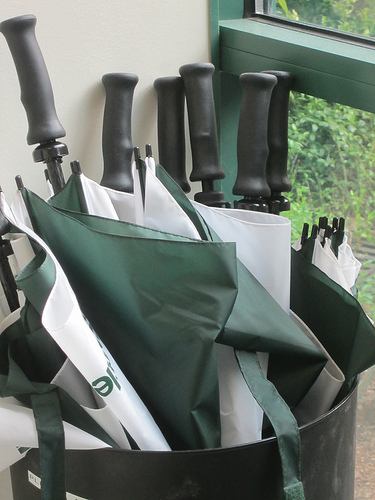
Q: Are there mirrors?
A: No, there are no mirrors.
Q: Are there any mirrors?
A: No, there are no mirrors.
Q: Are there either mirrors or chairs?
A: No, there are no mirrors or chairs.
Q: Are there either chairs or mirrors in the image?
A: No, there are no mirrors or chairs.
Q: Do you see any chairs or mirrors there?
A: No, there are no mirrors or chairs.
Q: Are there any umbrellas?
A: Yes, there is an umbrella.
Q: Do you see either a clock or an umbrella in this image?
A: Yes, there is an umbrella.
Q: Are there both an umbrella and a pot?
A: No, there is an umbrella but no pots.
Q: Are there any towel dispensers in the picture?
A: No, there are no towel dispensers.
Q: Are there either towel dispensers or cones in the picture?
A: No, there are no towel dispensers or cones.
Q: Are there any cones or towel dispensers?
A: No, there are no towel dispensers or cones.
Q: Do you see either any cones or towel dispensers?
A: No, there are no towel dispensers or cones.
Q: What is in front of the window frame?
A: The umbrella is in front of the window frame.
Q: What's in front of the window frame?
A: The umbrella is in front of the window frame.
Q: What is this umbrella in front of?
A: The umbrella is in front of the window frame.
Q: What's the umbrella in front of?
A: The umbrella is in front of the window frame.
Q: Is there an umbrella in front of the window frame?
A: Yes, there is an umbrella in front of the window frame.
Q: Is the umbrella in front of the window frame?
A: Yes, the umbrella is in front of the window frame.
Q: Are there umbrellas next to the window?
A: Yes, there is an umbrella next to the window.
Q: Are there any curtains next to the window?
A: No, there is an umbrella next to the window.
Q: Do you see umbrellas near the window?
A: Yes, there is an umbrella near the window.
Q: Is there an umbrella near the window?
A: Yes, there is an umbrella near the window.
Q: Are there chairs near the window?
A: No, there is an umbrella near the window.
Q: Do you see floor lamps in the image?
A: No, there are no floor lamps.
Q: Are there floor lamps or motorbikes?
A: No, there are no floor lamps or motorbikes.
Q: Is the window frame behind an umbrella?
A: Yes, the window frame is behind an umbrella.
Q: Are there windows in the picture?
A: Yes, there is a window.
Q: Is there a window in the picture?
A: Yes, there is a window.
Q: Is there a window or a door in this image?
A: Yes, there is a window.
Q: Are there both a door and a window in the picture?
A: No, there is a window but no doors.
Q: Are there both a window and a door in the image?
A: No, there is a window but no doors.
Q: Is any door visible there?
A: No, there are no doors.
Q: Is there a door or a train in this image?
A: No, there are no doors or trains.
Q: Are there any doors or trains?
A: No, there are no doors or trains.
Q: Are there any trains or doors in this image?
A: No, there are no doors or trains.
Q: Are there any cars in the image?
A: No, there are no cars.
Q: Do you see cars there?
A: No, there are no cars.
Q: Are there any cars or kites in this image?
A: No, there are no cars or kites.